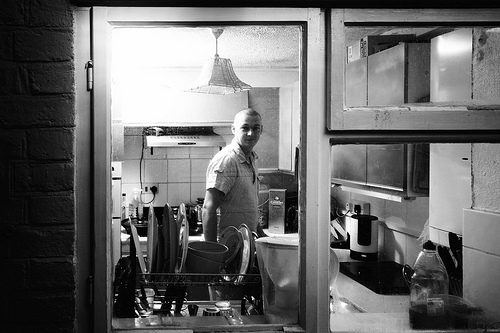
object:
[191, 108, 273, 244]
man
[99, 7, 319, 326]
window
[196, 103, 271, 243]
man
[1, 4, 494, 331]
house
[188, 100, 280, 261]
man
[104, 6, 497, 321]
kitchen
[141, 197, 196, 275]
plate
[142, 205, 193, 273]
plates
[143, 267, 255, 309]
drainer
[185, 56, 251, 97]
light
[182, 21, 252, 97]
light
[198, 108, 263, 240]
man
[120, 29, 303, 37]
ceiling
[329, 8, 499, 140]
cabinet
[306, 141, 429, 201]
cabinet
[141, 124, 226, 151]
vent hood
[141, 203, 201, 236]
stove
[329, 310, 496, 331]
table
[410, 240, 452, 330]
bottle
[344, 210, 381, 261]
kettle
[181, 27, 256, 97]
light fixture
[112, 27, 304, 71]
ceiling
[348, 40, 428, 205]
wood cabinets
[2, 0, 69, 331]
wall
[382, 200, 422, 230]
tile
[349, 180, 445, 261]
wall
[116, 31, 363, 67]
ceiling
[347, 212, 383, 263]
cylinder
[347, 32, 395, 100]
panes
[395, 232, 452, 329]
skateboard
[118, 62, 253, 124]
cabinet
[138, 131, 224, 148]
light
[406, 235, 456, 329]
glass bottle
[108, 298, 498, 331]
counter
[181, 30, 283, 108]
light fixture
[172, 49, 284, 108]
light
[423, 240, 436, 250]
cap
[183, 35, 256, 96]
light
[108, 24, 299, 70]
ceiling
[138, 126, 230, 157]
vent hood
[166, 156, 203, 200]
tiles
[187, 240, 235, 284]
pot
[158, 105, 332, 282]
looking out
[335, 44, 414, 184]
wood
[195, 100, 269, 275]
man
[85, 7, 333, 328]
window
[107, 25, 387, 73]
ceiling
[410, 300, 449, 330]
liquid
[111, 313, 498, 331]
window sill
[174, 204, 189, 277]
plate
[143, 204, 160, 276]
plate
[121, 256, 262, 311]
rack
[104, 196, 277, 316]
drainer